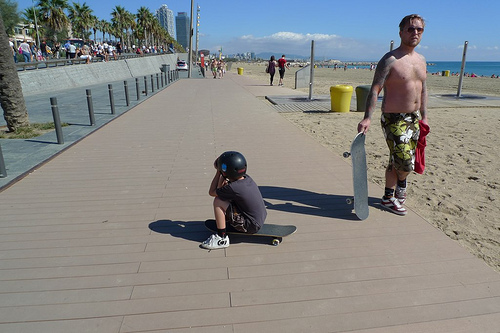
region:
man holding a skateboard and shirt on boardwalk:
[340, 7, 430, 217]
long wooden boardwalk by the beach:
[3, 66, 498, 331]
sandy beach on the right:
[233, 60, 498, 270]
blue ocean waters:
[343, 62, 497, 78]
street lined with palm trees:
[25, 2, 185, 57]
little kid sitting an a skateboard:
[200, 150, 297, 257]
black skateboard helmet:
[210, 152, 247, 177]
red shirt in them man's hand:
[414, 124, 430, 174]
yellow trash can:
[327, 82, 353, 112]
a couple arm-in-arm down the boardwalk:
[268, 53, 287, 87]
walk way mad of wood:
[129, 123, 180, 320]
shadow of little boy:
[151, 215, 198, 242]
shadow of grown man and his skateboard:
[268, 184, 350, 214]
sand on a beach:
[453, 128, 493, 230]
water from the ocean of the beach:
[443, 58, 486, 68]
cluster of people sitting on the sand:
[435, 68, 496, 77]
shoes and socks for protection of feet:
[378, 183, 413, 217]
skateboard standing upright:
[345, 132, 372, 219]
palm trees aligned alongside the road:
[27, 6, 170, 46]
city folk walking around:
[1, 38, 130, 53]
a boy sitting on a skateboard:
[199, 149, 296, 251]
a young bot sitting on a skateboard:
[199, 150, 296, 250]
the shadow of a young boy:
[149, 214, 217, 243]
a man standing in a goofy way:
[358, 14, 428, 217]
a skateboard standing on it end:
[342, 126, 370, 228]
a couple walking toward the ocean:
[263, 53, 289, 88]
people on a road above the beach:
[9, 37, 176, 71]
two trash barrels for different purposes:
[327, 83, 374, 114]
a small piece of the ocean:
[327, 60, 498, 77]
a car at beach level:
[176, 59, 188, 71]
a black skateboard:
[342, 133, 373, 220]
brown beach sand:
[289, 105, 499, 265]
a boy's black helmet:
[211, 148, 250, 183]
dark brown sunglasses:
[403, 24, 425, 32]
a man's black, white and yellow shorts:
[372, 110, 422, 170]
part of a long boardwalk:
[0, 65, 495, 330]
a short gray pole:
[45, 92, 65, 145]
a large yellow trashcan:
[326, 82, 353, 109]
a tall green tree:
[107, 3, 135, 43]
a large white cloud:
[233, 25, 373, 60]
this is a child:
[140, 129, 282, 259]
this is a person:
[350, 12, 474, 224]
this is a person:
[254, 46, 292, 103]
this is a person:
[275, 36, 293, 86]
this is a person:
[185, 36, 216, 84]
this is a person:
[201, 48, 236, 98]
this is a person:
[47, 6, 78, 63]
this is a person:
[70, 32, 92, 69]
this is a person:
[118, 26, 162, 53]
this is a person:
[15, 22, 57, 64]